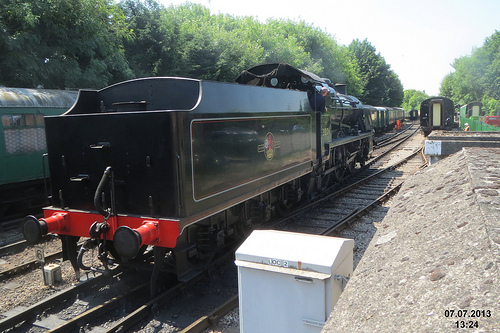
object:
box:
[217, 224, 363, 333]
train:
[15, 58, 387, 293]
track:
[0, 117, 427, 332]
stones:
[3, 274, 50, 303]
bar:
[16, 205, 184, 261]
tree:
[340, 32, 410, 111]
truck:
[476, 115, 499, 130]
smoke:
[267, 39, 357, 95]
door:
[429, 100, 444, 128]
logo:
[255, 130, 285, 164]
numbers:
[443, 309, 450, 319]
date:
[469, 308, 492, 319]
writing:
[452, 319, 485, 330]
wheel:
[273, 180, 303, 218]